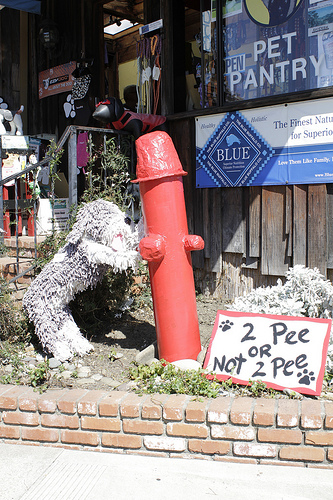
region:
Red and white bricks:
[132, 406, 240, 463]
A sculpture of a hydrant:
[130, 142, 201, 358]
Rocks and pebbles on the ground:
[44, 361, 94, 381]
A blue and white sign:
[192, 118, 289, 201]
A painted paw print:
[295, 364, 314, 393]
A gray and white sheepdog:
[21, 202, 135, 368]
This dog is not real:
[22, 194, 146, 358]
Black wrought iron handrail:
[15, 121, 83, 211]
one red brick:
[281, 444, 325, 468]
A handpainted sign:
[206, 305, 308, 372]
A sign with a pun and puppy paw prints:
[199, 308, 330, 395]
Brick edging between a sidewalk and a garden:
[1, 382, 332, 470]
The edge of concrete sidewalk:
[0, 440, 332, 496]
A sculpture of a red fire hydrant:
[129, 130, 203, 365]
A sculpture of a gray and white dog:
[21, 198, 140, 362]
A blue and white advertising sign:
[194, 93, 331, 188]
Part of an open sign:
[219, 53, 245, 76]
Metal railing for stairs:
[1, 124, 143, 288]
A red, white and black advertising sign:
[37, 61, 76, 99]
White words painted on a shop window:
[228, 30, 324, 91]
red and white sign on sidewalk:
[205, 299, 327, 395]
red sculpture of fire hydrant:
[132, 127, 207, 367]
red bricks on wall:
[101, 407, 140, 452]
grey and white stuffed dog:
[13, 181, 140, 367]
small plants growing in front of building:
[130, 363, 200, 400]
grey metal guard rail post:
[63, 126, 79, 202]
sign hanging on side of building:
[191, 108, 329, 186]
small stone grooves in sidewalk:
[33, 457, 103, 498]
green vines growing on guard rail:
[35, 127, 66, 243]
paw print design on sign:
[288, 367, 321, 388]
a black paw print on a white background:
[217, 319, 233, 330]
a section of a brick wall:
[82, 413, 251, 453]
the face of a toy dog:
[81, 201, 137, 268]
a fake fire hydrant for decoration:
[137, 131, 201, 359]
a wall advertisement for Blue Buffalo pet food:
[195, 97, 332, 185]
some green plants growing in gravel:
[142, 368, 190, 387]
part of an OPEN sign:
[223, 54, 243, 73]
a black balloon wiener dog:
[92, 99, 170, 132]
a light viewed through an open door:
[103, 16, 147, 36]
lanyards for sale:
[137, 41, 157, 112]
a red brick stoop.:
[0, 396, 316, 449]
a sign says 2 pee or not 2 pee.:
[195, 307, 329, 392]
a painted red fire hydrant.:
[128, 126, 212, 366]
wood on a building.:
[203, 186, 329, 268]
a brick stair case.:
[0, 168, 38, 326]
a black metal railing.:
[0, 140, 69, 265]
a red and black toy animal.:
[90, 93, 178, 136]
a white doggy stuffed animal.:
[15, 198, 145, 363]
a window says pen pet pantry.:
[202, 1, 331, 108]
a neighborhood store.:
[0, 1, 332, 494]